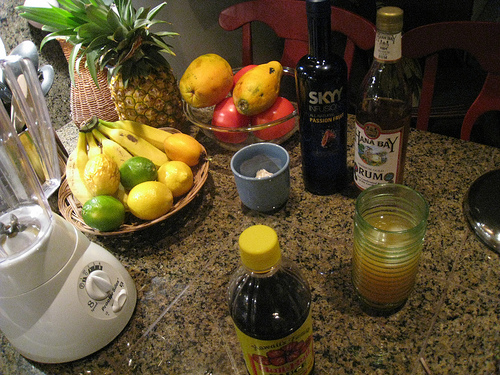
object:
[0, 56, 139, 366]
blender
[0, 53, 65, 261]
pitcher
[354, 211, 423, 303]
orange juice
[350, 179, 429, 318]
glass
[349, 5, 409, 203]
bottle of rum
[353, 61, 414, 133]
glass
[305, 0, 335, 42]
bottle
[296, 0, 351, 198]
vodka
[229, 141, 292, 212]
coffee mug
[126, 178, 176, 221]
lemon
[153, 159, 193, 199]
lemon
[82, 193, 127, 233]
lime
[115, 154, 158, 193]
lime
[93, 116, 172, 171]
bananas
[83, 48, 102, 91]
leaves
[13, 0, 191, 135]
pineapple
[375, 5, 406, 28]
cap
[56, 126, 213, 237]
basket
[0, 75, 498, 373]
countertop